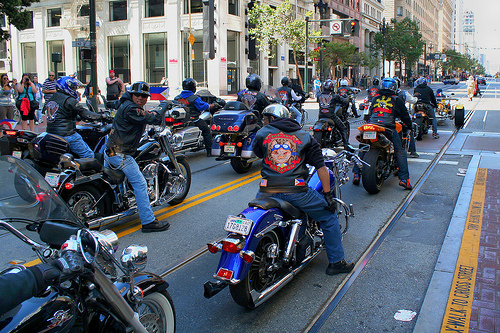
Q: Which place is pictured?
A: It is a road.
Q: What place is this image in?
A: It is at the road.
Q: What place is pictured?
A: It is a road.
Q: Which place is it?
A: It is a road.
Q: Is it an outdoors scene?
A: Yes, it is outdoors.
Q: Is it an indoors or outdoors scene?
A: It is outdoors.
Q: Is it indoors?
A: No, it is outdoors.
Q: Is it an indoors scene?
A: No, it is outdoors.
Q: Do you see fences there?
A: No, there are no fences.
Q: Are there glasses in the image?
A: No, there are no glasses.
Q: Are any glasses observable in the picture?
A: No, there are no glasses.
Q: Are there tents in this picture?
A: No, there are no tents.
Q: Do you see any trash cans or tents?
A: No, there are no tents or trash cans.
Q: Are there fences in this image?
A: No, there are no fences.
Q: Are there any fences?
A: No, there are no fences.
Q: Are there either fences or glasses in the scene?
A: No, there are no fences or glasses.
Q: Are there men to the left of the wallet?
A: Yes, there is a man to the left of the wallet.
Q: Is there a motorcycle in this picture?
A: Yes, there is a motorcycle.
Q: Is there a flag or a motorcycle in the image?
A: Yes, there is a motorcycle.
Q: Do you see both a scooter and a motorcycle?
A: No, there is a motorcycle but no scooters.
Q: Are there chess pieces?
A: No, there are no chess pieces.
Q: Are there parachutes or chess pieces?
A: No, there are no chess pieces or parachutes.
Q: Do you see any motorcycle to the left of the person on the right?
A: Yes, there is a motorcycle to the left of the person.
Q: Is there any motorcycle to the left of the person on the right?
A: Yes, there is a motorcycle to the left of the person.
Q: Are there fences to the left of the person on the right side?
A: No, there is a motorcycle to the left of the person.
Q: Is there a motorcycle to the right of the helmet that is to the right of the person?
A: Yes, there is a motorcycle to the right of the helmet.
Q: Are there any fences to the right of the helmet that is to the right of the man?
A: No, there is a motorcycle to the right of the helmet.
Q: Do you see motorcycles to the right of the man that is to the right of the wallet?
A: Yes, there is a motorcycle to the right of the man.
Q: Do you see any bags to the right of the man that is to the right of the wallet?
A: No, there is a motorcycle to the right of the man.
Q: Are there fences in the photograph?
A: No, there are no fences.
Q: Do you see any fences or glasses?
A: No, there are no fences or glasses.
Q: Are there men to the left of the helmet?
A: Yes, there is a man to the left of the helmet.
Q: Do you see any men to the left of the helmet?
A: Yes, there is a man to the left of the helmet.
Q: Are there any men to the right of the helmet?
A: No, the man is to the left of the helmet.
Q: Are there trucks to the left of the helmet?
A: No, there is a man to the left of the helmet.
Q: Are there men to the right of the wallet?
A: Yes, there is a man to the right of the wallet.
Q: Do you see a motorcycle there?
A: Yes, there is a motorcycle.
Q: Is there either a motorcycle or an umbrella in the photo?
A: Yes, there is a motorcycle.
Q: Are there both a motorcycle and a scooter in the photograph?
A: No, there is a motorcycle but no scooters.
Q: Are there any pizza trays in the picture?
A: No, there are no pizza trays.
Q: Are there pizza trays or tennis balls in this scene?
A: No, there are no pizza trays or tennis balls.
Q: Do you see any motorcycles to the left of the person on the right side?
A: Yes, there is a motorcycle to the left of the person.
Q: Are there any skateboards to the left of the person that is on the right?
A: No, there is a motorcycle to the left of the person.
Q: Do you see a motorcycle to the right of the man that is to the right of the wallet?
A: Yes, there is a motorcycle to the right of the man.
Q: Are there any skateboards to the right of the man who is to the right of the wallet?
A: No, there is a motorcycle to the right of the man.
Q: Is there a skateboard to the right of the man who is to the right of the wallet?
A: No, there is a motorcycle to the right of the man.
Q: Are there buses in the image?
A: No, there are no buses.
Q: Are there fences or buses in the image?
A: No, there are no buses or fences.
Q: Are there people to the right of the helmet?
A: Yes, there is a person to the right of the helmet.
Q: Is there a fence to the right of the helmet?
A: No, there is a person to the right of the helmet.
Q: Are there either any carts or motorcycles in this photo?
A: Yes, there is a motorcycle.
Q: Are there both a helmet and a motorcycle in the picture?
A: Yes, there are both a motorcycle and a helmet.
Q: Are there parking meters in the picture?
A: No, there are no parking meters.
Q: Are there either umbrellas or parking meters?
A: No, there are no parking meters or umbrellas.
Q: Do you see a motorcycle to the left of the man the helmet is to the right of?
A: Yes, there is a motorcycle to the left of the man.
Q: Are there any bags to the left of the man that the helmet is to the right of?
A: No, there is a motorcycle to the left of the man.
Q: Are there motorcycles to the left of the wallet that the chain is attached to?
A: Yes, there is a motorcycle to the left of the wallet.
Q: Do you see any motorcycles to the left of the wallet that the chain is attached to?
A: Yes, there is a motorcycle to the left of the wallet.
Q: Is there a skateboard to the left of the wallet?
A: No, there is a motorcycle to the left of the wallet.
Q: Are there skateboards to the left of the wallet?
A: No, there is a motorcycle to the left of the wallet.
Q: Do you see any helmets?
A: Yes, there is a helmet.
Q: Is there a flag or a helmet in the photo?
A: Yes, there is a helmet.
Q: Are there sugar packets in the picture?
A: No, there are no sugar packets.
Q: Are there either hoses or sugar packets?
A: No, there are no sugar packets or hoses.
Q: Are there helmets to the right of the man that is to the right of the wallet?
A: Yes, there is a helmet to the right of the man.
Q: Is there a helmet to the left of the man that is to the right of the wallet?
A: No, the helmet is to the right of the man.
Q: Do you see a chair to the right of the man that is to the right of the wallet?
A: No, there is a helmet to the right of the man.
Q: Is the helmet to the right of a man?
A: Yes, the helmet is to the right of a man.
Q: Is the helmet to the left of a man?
A: No, the helmet is to the right of a man.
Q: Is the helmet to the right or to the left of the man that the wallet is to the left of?
A: The helmet is to the right of the man.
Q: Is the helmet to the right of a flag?
A: No, the helmet is to the right of a motorcycle.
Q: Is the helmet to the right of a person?
A: Yes, the helmet is to the right of a person.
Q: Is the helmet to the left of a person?
A: No, the helmet is to the right of a person.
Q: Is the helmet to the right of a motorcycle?
A: Yes, the helmet is to the right of a motorcycle.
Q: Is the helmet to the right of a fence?
A: No, the helmet is to the right of a motorcycle.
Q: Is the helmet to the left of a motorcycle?
A: No, the helmet is to the right of a motorcycle.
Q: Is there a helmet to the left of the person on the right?
A: Yes, there is a helmet to the left of the person.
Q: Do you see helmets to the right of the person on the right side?
A: No, the helmet is to the left of the person.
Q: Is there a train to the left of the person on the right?
A: No, there is a helmet to the left of the person.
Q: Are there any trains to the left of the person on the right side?
A: No, there is a helmet to the left of the person.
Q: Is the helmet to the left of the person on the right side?
A: Yes, the helmet is to the left of the person.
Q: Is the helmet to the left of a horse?
A: No, the helmet is to the left of the person.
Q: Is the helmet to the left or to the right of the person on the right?
A: The helmet is to the left of the person.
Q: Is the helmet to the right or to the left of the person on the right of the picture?
A: The helmet is to the left of the person.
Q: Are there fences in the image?
A: No, there are no fences.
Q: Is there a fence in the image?
A: No, there are no fences.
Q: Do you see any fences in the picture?
A: No, there are no fences.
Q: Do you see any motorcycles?
A: Yes, there is a motorcycle.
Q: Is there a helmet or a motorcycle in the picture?
A: Yes, there is a motorcycle.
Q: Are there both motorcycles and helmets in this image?
A: Yes, there are both a motorcycle and a helmet.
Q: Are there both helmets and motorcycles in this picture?
A: Yes, there are both a motorcycle and a helmet.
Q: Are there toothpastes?
A: No, there are no toothpastes.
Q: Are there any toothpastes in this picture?
A: No, there are no toothpastes.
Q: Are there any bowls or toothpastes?
A: No, there are no toothpastes or bowls.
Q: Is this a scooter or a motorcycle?
A: This is a motorcycle.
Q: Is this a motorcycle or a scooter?
A: This is a motorcycle.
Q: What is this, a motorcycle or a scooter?
A: This is a motorcycle.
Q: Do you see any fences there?
A: No, there are no fences.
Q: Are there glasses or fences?
A: No, there are no fences or glasses.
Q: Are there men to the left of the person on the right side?
A: Yes, there is a man to the left of the person.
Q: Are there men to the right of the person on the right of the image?
A: No, the man is to the left of the person.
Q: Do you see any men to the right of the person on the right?
A: No, the man is to the left of the person.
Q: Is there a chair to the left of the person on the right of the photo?
A: No, there is a man to the left of the person.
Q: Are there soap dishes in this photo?
A: No, there are no soap dishes.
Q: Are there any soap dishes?
A: No, there are no soap dishes.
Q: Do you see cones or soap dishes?
A: No, there are no soap dishes or cones.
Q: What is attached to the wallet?
A: The chain is attached to the wallet.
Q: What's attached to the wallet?
A: The chain is attached to the wallet.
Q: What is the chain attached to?
A: The chain is attached to the wallet.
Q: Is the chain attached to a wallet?
A: Yes, the chain is attached to a wallet.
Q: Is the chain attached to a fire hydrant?
A: No, the chain is attached to a wallet.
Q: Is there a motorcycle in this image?
A: Yes, there is a motorcycle.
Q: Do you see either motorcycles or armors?
A: Yes, there is a motorcycle.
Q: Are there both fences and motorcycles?
A: No, there is a motorcycle but no fences.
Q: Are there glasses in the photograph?
A: No, there are no glasses.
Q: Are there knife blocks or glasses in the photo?
A: No, there are no glasses or knife blocks.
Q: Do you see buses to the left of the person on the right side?
A: No, there is a motorcycle to the left of the person.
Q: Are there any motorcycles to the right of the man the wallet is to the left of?
A: Yes, there is a motorcycle to the right of the man.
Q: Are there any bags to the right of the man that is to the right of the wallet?
A: No, there is a motorcycle to the right of the man.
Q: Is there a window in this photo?
A: Yes, there are windows.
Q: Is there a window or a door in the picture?
A: Yes, there are windows.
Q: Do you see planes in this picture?
A: No, there are no planes.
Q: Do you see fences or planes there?
A: No, there are no planes or fences.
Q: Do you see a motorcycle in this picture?
A: Yes, there is a motorcycle.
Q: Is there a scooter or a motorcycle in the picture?
A: Yes, there is a motorcycle.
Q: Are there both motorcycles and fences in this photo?
A: No, there is a motorcycle but no fences.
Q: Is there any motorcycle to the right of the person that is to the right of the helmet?
A: Yes, there is a motorcycle to the right of the person.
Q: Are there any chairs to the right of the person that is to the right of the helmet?
A: No, there is a motorcycle to the right of the person.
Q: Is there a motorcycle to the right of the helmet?
A: Yes, there is a motorcycle to the right of the helmet.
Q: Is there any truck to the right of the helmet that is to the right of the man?
A: No, there is a motorcycle to the right of the helmet.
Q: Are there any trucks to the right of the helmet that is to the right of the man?
A: No, there is a motorcycle to the right of the helmet.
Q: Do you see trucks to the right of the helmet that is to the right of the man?
A: No, there is a motorcycle to the right of the helmet.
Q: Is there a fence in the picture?
A: No, there are no fences.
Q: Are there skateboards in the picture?
A: No, there are no skateboards.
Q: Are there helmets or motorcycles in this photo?
A: Yes, there is a motorcycle.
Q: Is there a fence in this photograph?
A: No, there are no fences.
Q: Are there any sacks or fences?
A: No, there are no fences or sacks.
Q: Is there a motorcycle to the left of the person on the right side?
A: Yes, there is a motorcycle to the left of the person.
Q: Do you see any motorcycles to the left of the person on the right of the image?
A: Yes, there is a motorcycle to the left of the person.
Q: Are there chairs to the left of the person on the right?
A: No, there is a motorcycle to the left of the person.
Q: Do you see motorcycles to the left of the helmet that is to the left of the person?
A: Yes, there is a motorcycle to the left of the helmet.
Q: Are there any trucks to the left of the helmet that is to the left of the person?
A: No, there is a motorcycle to the left of the helmet.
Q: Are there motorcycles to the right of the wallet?
A: Yes, there is a motorcycle to the right of the wallet.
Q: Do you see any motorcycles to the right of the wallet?
A: Yes, there is a motorcycle to the right of the wallet.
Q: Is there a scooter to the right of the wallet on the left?
A: No, there is a motorcycle to the right of the wallet.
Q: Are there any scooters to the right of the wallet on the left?
A: No, there is a motorcycle to the right of the wallet.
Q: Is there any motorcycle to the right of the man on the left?
A: Yes, there is a motorcycle to the right of the man.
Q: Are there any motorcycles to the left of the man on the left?
A: No, the motorcycle is to the right of the man.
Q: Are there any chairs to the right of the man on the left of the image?
A: No, there is a motorcycle to the right of the man.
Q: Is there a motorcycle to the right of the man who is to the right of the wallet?
A: Yes, there is a motorcycle to the right of the man.